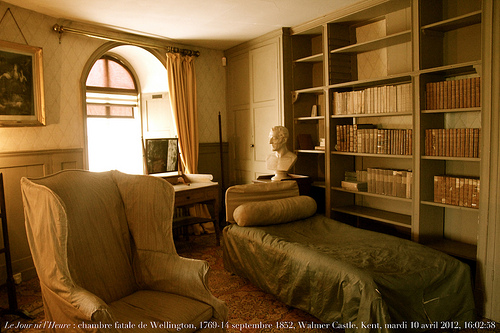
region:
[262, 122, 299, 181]
Bust in front of bookshelf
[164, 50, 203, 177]
Curtain behind monitor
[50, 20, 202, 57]
Steel curtain rod above desk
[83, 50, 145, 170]
Large arched window behind desk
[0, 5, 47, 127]
Picture frame next to curtain rod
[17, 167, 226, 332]
Sofa chair is covered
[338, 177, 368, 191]
Book on large bookshelf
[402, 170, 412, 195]
Book on large bookshelf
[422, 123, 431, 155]
Book on large bookshelf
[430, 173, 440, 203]
Book on large bookshelf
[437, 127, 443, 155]
book on the shelf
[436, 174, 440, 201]
book on the shelf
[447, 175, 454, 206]
book on the shelf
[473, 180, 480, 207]
book on the shelf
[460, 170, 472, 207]
book on the shelf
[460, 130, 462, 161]
book on the shelf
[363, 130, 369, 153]
book on the shelf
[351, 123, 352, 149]
book on the shelf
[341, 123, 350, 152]
book on the shelf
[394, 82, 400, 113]
book on the shelf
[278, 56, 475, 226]
the book shelf has books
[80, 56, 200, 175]
the window is open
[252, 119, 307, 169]
the statue is a head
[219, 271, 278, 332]
the ground is carpetd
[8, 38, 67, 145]
picture is on the wall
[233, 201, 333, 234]
the pillow is white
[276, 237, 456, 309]
the bedshhet is green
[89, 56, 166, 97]
the window is arched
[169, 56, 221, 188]
the curatin is orange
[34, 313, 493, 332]
the letters are white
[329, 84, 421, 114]
books on a book shelf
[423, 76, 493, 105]
books on a book shelf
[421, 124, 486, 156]
books on a book shelf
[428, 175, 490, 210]
books on a book shelf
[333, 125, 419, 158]
books on a book shelf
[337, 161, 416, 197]
books on a book shelf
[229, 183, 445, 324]
a day bed by a book shelf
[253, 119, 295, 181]
a bust of a man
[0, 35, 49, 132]
a framed picture on a wall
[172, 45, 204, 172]
a curtain on a window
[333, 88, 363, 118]
books in the shelf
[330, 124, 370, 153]
books in the shelf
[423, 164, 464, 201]
books in the shelf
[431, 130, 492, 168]
books in the shelf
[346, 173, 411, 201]
books in the shelf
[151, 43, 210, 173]
the curtain is drawn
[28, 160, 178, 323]
the chair is empty